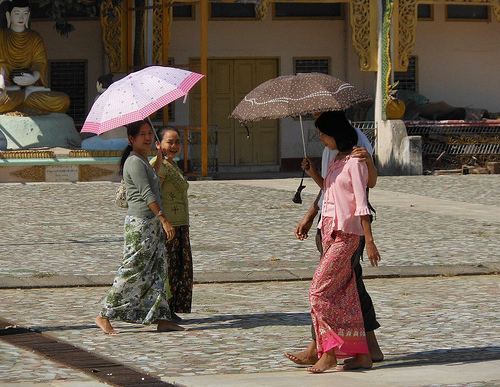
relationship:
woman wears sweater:
[297, 112, 381, 375] [316, 157, 376, 234]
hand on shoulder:
[352, 147, 369, 161] [346, 148, 367, 168]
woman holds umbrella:
[297, 112, 381, 375] [236, 70, 369, 165]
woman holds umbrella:
[99, 123, 188, 334] [81, 65, 207, 160]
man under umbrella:
[307, 107, 382, 177] [236, 70, 369, 165]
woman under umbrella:
[297, 112, 381, 375] [236, 70, 369, 165]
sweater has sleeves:
[316, 157, 376, 234] [352, 162, 374, 221]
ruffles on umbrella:
[230, 101, 367, 123] [236, 70, 369, 165]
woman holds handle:
[297, 112, 381, 375] [297, 113, 311, 159]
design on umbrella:
[242, 83, 361, 105] [236, 70, 369, 165]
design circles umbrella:
[242, 83, 361, 105] [236, 70, 369, 165]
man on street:
[307, 107, 382, 177] [3, 176, 499, 385]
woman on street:
[297, 112, 381, 375] [3, 176, 499, 385]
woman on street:
[99, 123, 188, 334] [3, 176, 499, 385]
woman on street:
[147, 130, 192, 333] [3, 176, 499, 385]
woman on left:
[99, 123, 188, 334] [3, 6, 260, 384]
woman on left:
[147, 130, 192, 333] [3, 6, 260, 384]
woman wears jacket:
[99, 123, 188, 334] [119, 157, 164, 221]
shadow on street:
[177, 308, 322, 329] [3, 176, 499, 385]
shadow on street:
[371, 343, 499, 370] [3, 176, 499, 385]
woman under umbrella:
[99, 123, 188, 334] [81, 65, 207, 160]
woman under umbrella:
[147, 130, 192, 333] [81, 65, 207, 160]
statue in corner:
[2, 2, 107, 184] [2, 4, 202, 241]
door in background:
[188, 57, 282, 173] [1, 4, 496, 171]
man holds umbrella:
[307, 107, 382, 177] [236, 70, 369, 165]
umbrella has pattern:
[236, 70, 369, 165] [242, 83, 361, 105]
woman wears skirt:
[297, 112, 381, 375] [311, 217, 370, 354]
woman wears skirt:
[99, 123, 188, 334] [106, 215, 177, 325]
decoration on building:
[348, 0, 422, 117] [56, 4, 498, 170]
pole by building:
[196, 8, 211, 171] [56, 4, 498, 170]